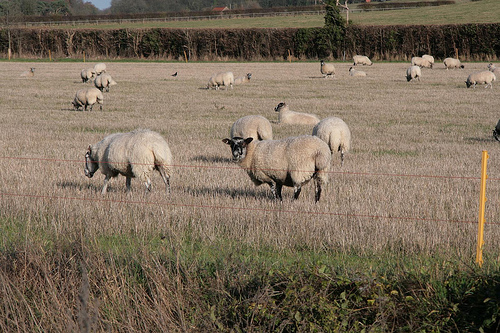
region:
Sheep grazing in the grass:
[18, 55, 498, 205]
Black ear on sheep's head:
[245, 136, 253, 142]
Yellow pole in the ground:
[474, 151, 489, 264]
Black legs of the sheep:
[275, 178, 323, 201]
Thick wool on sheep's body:
[253, 132, 335, 184]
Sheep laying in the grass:
[274, 101, 319, 126]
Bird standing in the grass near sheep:
[169, 70, 179, 77]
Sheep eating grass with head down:
[70, 85, 105, 110]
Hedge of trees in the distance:
[1, 15, 499, 61]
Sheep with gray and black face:
[221, 135, 331, 202]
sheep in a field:
[72, 127, 174, 181]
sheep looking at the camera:
[208, 125, 337, 199]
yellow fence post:
[475, 145, 492, 276]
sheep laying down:
[268, 94, 330, 130]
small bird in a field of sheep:
[162, 70, 189, 85]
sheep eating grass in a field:
[55, 79, 108, 108]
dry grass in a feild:
[353, 88, 403, 131]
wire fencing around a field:
[443, 164, 480, 231]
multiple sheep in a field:
[396, 46, 489, 93]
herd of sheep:
[21, 63, 499, 181]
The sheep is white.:
[305, 55, 345, 85]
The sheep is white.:
[336, 61, 373, 81]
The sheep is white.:
[340, 46, 376, 66]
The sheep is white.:
[386, 60, 426, 80]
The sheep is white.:
[191, 66, 232, 91]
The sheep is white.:
[265, 90, 320, 125]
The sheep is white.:
[220, 125, 335, 202]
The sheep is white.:
[65, 117, 190, 203]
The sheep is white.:
[55, 83, 135, 116]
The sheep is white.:
[447, 64, 499, 92]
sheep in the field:
[78, 128, 179, 191]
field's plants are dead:
[385, 175, 450, 235]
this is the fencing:
[310, 165, 483, 259]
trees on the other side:
[214, 25, 305, 60]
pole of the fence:
[457, 132, 490, 269]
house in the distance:
[204, 4, 238, 19]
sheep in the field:
[70, 56, 99, 115]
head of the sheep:
[216, 128, 249, 162]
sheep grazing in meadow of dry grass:
[0, 58, 499, 238]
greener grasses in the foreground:
[12, 239, 499, 331]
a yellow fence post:
[478, 150, 484, 272]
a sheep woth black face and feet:
[221, 124, 337, 202]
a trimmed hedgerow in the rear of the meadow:
[7, 24, 498, 68]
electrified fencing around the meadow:
[1, 151, 478, 229]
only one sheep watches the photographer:
[220, 132, 330, 202]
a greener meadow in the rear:
[1, 0, 499, 24]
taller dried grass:
[0, 211, 195, 332]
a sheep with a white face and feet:
[83, 135, 177, 195]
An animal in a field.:
[233, 136, 350, 193]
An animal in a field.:
[217, 113, 268, 162]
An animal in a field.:
[272, 100, 314, 129]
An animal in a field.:
[311, 114, 356, 161]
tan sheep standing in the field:
[84, 127, 174, 194]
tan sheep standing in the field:
[223, 135, 333, 202]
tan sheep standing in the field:
[230, 114, 274, 142]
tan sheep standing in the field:
[313, 114, 352, 166]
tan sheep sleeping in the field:
[271, 98, 322, 130]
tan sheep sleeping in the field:
[234, 71, 251, 84]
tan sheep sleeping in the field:
[345, 66, 367, 77]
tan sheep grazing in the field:
[71, 85, 103, 110]